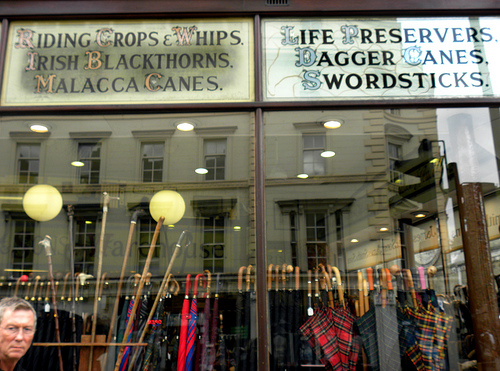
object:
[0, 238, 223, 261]
sign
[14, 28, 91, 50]
letters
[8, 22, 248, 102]
font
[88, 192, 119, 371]
canes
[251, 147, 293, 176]
ground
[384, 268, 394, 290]
orange handle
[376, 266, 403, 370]
umbrella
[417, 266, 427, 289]
handle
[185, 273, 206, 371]
umbrella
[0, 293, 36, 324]
hair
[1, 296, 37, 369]
head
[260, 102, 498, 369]
reflection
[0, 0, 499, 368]
building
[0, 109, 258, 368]
reflection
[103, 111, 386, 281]
giraffe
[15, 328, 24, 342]
nose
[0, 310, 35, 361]
face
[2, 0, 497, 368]
storefront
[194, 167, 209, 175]
lights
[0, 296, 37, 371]
man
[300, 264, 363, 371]
umbrella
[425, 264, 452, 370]
umbrella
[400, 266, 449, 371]
umbrella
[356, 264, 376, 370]
umbrella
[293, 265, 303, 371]
umbrella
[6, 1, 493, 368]
store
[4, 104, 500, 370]
store window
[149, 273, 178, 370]
umbrellas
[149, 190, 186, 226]
globe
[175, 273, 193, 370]
umbrella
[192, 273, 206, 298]
handle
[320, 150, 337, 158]
ligts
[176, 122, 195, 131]
lighting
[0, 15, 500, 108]
sign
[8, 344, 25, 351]
mouth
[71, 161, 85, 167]
light fixture